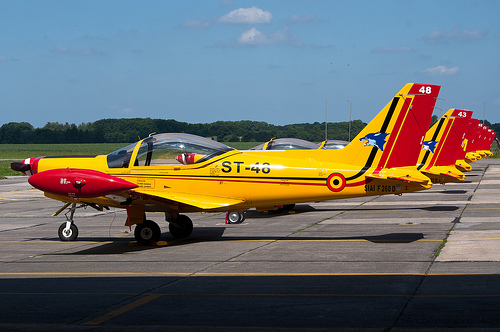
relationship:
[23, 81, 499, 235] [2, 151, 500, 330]
planes on runway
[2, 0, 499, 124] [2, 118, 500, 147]
sky above trees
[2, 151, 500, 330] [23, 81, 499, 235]
runway under planes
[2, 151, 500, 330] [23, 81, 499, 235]
runway below planes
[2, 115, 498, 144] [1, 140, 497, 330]
forest around area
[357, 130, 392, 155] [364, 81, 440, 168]
wolf on tail wing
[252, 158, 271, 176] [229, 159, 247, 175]
number on letter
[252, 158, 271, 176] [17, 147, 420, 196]
number on side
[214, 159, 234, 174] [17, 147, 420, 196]
letter on side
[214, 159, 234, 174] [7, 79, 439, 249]
letter on plane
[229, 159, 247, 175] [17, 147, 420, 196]
letter on side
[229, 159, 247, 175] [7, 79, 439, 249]
letter on plane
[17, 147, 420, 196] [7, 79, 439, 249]
side of plane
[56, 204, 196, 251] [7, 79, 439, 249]
landing gear under plane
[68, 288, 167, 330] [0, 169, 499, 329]
line on pavement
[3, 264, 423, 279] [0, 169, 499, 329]
line on pavement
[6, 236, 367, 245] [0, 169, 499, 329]
line on pavement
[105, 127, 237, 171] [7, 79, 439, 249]
window on top of plane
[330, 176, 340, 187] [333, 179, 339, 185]
circle around dot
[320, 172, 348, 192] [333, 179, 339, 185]
circle around dot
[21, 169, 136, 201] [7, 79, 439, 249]
engine on plane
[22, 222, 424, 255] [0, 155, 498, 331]
shadow on ground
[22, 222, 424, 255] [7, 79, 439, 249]
shadow from plane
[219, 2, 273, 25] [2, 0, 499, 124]
cloud in sky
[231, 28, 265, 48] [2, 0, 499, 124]
cloud in sky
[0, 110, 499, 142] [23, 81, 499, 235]
trees behind planes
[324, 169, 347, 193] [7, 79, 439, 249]
design on plane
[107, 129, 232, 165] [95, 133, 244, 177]
glass around cockpit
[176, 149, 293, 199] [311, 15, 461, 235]
logo on tail